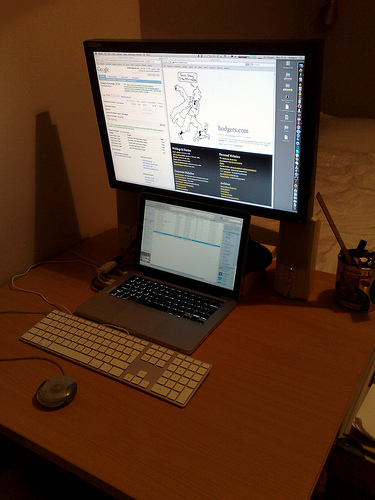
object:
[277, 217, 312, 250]
speaker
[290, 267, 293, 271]
light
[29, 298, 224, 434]
flat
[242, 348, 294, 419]
desk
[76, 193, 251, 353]
laptop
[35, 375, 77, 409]
mouse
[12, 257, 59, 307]
cord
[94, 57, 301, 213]
screen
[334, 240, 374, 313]
cup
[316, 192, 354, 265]
pencils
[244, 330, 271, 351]
brown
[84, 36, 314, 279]
computer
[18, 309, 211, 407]
keyboard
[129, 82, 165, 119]
paper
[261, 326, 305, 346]
wooden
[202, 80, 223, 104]
white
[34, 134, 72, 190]
shadow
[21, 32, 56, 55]
wall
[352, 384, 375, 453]
pile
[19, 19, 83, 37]
tan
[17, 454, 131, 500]
edge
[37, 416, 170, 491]
table